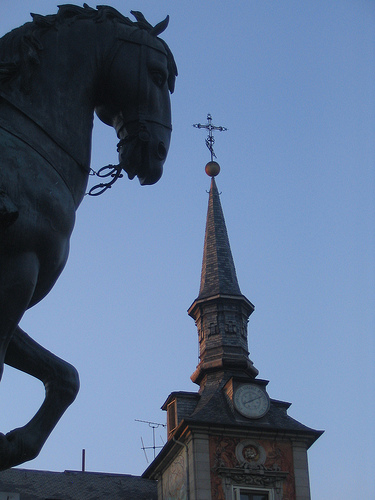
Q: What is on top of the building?
A: The cross.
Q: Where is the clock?
A: On the building.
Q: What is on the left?
A: Horse statue.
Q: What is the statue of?
A: The horse.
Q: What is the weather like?
A: Clear skies.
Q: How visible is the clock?
A: Very visible.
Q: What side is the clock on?
A: Front.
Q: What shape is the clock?
A: Circle.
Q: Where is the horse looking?
A: To the right.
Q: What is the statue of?
A: Horse.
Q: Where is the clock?
A: Building.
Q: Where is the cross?
A: Above the clock.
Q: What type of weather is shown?
A: Clear.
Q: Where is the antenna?
A: Roof.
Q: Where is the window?
A: Below the clock.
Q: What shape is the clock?
A: Round.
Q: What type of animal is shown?
A: Horse.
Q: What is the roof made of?
A: Shingles.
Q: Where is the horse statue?
A: On the left side of the photo.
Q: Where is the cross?
A: On top of the building.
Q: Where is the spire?
A: On top of the building above the clock.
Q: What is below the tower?
A: A clock.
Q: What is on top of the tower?
A: A cross.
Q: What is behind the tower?
A: An antenna.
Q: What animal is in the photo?
A: Horse.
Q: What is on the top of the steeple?
A: Cross.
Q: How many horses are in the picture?
A: 1.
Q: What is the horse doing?
A: Galloping.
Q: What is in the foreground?
A: Church.